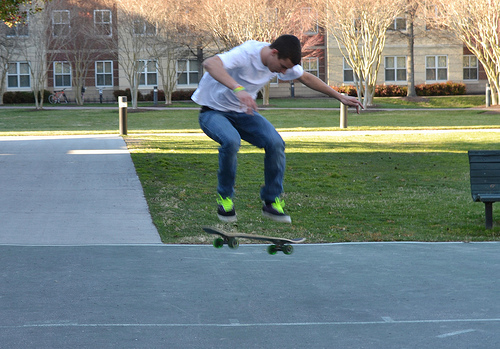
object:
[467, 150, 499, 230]
bench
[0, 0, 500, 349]
park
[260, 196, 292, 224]
shoe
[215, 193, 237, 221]
shoe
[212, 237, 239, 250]
tires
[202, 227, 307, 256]
board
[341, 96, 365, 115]
hand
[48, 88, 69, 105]
bike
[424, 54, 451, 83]
window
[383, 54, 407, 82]
window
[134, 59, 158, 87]
window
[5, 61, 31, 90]
window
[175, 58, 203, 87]
window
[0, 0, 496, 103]
building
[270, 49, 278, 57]
ear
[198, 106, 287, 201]
jeans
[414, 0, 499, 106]
tree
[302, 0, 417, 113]
tree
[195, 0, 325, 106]
tree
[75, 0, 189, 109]
tree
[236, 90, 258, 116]
hand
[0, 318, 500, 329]
white lines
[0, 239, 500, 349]
pavement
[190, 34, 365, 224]
man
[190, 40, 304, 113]
shirt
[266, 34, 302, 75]
head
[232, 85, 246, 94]
band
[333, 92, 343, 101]
wrist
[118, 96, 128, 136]
pole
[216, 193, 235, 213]
laces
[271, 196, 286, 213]
laces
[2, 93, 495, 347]
ground